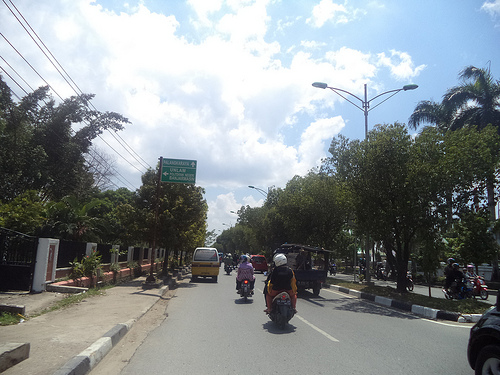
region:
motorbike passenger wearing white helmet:
[261, 250, 300, 320]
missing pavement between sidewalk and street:
[134, 305, 171, 332]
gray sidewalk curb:
[103, 317, 131, 344]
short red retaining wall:
[72, 263, 143, 288]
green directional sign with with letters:
[156, 151, 201, 187]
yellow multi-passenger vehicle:
[188, 242, 223, 287]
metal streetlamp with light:
[241, 176, 274, 203]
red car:
[247, 249, 272, 276]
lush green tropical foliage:
[23, 187, 133, 232]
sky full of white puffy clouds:
[126, 0, 305, 143]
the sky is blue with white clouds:
[5, 2, 496, 222]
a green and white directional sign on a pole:
[143, 154, 203, 285]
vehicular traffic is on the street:
[181, 237, 498, 373]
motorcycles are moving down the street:
[235, 252, 300, 328]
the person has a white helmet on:
[271, 253, 289, 267]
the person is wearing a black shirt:
[269, 266, 294, 290]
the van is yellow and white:
[188, 244, 222, 284]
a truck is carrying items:
[278, 242, 332, 300]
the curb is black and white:
[61, 280, 485, 373]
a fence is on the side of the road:
[7, 233, 185, 290]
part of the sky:
[398, 6, 427, 44]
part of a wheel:
[269, 290, 291, 331]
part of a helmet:
[274, 255, 291, 275]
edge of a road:
[131, 314, 149, 336]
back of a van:
[183, 231, 219, 279]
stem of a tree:
[389, 262, 408, 284]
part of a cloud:
[216, 175, 234, 204]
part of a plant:
[69, 235, 107, 316]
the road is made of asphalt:
[209, 317, 247, 357]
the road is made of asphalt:
[206, 341, 234, 363]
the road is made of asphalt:
[217, 328, 251, 373]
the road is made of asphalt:
[203, 304, 258, 362]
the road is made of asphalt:
[230, 328, 265, 360]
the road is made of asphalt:
[237, 330, 275, 374]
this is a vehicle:
[187, 242, 221, 284]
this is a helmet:
[275, 252, 289, 262]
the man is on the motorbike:
[269, 255, 292, 293]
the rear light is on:
[241, 278, 249, 283]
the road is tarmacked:
[196, 297, 253, 357]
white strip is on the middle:
[312, 322, 347, 349]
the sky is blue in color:
[430, 15, 464, 46]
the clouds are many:
[144, 55, 274, 115]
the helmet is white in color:
[275, 255, 287, 265]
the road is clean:
[353, 322, 395, 355]